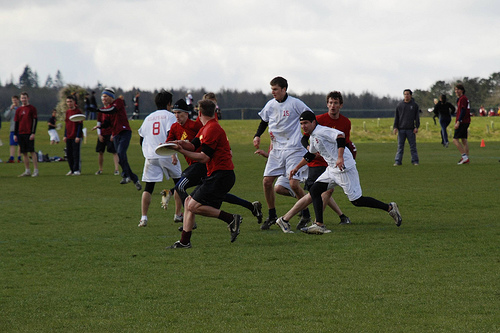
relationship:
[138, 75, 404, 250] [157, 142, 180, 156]
people have a frisbee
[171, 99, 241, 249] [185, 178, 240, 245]
person has a leg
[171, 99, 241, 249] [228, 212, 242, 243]
person has a shoe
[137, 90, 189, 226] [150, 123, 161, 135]
person has a number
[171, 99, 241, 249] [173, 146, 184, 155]
person has a hand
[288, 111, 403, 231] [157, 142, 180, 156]
man has a frisbee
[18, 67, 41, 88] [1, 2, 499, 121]
tree in background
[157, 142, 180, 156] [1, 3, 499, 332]
frisbee in air